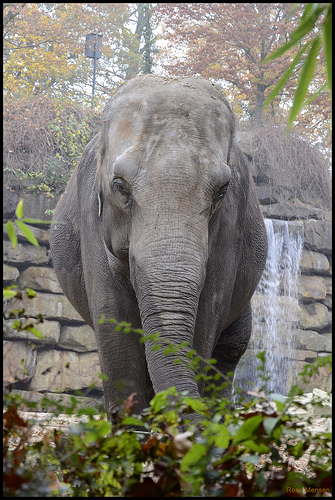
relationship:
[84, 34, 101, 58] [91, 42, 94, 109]
sign on post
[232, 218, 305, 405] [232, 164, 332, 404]
waterfall on rocks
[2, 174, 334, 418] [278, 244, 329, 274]
wall made of stone